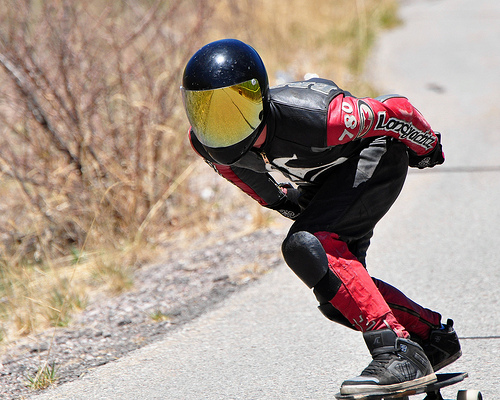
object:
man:
[181, 37, 462, 395]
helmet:
[180, 37, 269, 166]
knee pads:
[279, 229, 331, 289]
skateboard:
[330, 369, 485, 400]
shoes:
[338, 328, 438, 394]